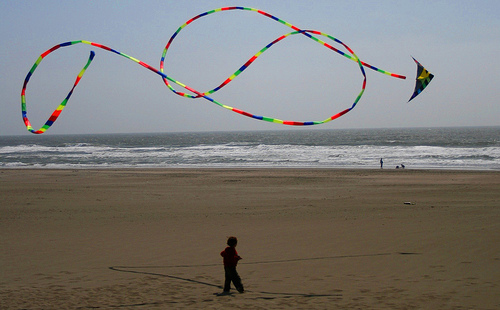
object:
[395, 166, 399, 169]
person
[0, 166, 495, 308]
beach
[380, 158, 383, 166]
person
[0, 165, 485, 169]
shore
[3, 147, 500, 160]
wave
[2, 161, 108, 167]
wave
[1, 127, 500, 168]
water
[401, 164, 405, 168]
person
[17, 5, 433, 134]
kite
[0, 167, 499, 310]
sand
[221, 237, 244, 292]
boy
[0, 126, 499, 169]
ocean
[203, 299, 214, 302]
footprints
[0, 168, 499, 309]
ground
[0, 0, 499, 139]
sky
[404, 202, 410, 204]
trash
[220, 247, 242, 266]
shirt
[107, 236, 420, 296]
shadow